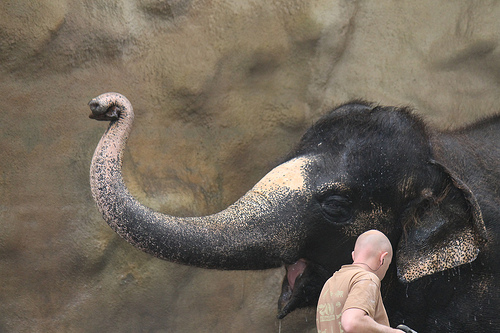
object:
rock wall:
[3, 274, 237, 333]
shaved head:
[351, 228, 397, 261]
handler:
[315, 229, 409, 333]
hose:
[396, 324, 417, 332]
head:
[276, 100, 486, 320]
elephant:
[70, 78, 499, 330]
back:
[432, 116, 494, 182]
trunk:
[85, 91, 317, 270]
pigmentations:
[412, 250, 470, 264]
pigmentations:
[94, 152, 121, 209]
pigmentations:
[235, 202, 308, 230]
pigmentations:
[356, 210, 391, 226]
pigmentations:
[100, 95, 130, 121]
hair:
[301, 100, 431, 187]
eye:
[319, 192, 354, 223]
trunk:
[81, 87, 300, 271]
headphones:
[372, 259, 384, 271]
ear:
[379, 252, 387, 265]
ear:
[396, 161, 488, 285]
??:
[371, 136, 385, 156]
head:
[350, 229, 393, 281]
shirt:
[314, 265, 392, 332]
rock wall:
[2, 2, 499, 89]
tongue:
[287, 259, 307, 288]